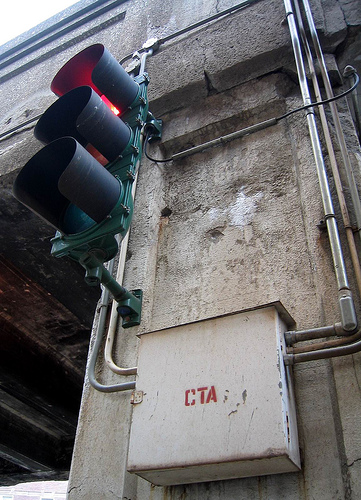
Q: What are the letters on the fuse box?
A: CTA.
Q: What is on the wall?
A: Traffic light.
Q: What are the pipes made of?
A: Metal.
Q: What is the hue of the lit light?
A: Red.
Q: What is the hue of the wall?
A: Gray.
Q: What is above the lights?
A: Wall.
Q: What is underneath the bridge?
A: Wood.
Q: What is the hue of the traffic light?
A: Black and green.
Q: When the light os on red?
A: That means stop.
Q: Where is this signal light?
A: On wall.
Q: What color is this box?
A: A cream color.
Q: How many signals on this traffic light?
A: Only three.